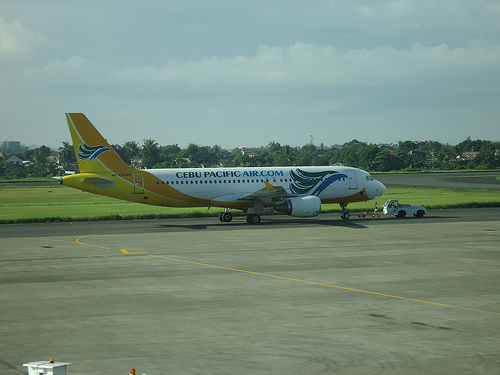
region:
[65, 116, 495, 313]
the plane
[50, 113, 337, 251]
the plane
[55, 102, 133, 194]
Orange and yellow tail on a plane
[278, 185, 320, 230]
White engine on a plane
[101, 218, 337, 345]
Gray pavement with yellow lines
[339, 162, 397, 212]
White nose on a plane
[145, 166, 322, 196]
Windows on a plane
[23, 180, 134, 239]
Green grass by a runway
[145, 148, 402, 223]
Orange, white and yellow airplane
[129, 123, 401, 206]
Trees by a runway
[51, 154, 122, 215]
Tail on a plane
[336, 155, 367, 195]
White door on a plane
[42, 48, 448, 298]
plane is yellow and white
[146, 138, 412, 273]
plane is yellow and white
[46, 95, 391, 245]
an airplane on a runway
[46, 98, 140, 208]
yellow and orange tail of a plane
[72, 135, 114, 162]
blue logo on tail of a plane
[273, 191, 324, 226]
silvery plane propeller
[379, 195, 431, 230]
a white truck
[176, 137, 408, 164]
green trees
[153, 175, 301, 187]
a row of windows on a plane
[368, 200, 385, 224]
person walking next to a plane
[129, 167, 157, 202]
cargo hold door of a plane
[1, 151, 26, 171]
roof of a white house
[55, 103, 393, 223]
a large passenger jet.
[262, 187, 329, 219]
a large jet engine.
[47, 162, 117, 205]
a rear side jet engine.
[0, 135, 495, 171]
a city with lots of trees.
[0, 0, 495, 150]
a cloudy blue sky.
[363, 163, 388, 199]
a cock pit of a plane.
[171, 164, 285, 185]
the name of a company.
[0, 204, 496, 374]
a runway at an airport.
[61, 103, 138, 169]
a tail fin of a jetliner.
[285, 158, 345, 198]
a picture on the side of a plane.